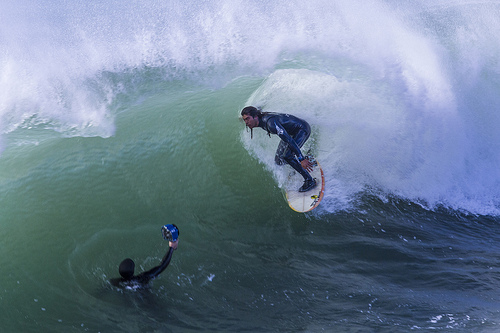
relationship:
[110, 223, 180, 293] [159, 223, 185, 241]
people has camera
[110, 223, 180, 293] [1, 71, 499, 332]
people in water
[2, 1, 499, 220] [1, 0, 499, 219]
wave has crest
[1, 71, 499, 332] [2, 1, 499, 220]
water getting pulled in wave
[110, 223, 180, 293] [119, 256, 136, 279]
people has head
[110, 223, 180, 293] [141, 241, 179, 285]
people has arm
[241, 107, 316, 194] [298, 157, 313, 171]
person has hand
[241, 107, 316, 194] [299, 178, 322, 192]
person has foot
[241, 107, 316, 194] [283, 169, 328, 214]
person on surfboard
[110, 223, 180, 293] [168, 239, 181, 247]
people has hand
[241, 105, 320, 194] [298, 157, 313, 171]
person has hand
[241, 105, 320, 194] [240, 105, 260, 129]
person has head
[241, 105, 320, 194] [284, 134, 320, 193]
person has leg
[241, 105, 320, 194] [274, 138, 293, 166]
person has leg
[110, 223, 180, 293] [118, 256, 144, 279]
people has hair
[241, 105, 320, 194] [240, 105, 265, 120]
person has hair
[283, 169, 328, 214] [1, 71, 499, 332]
surfboard in water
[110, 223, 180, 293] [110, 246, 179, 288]
people wearing wetsuit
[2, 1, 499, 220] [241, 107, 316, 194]
wave behind person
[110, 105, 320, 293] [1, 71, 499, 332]
people are in water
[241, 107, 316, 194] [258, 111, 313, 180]
person wearing bodysuit